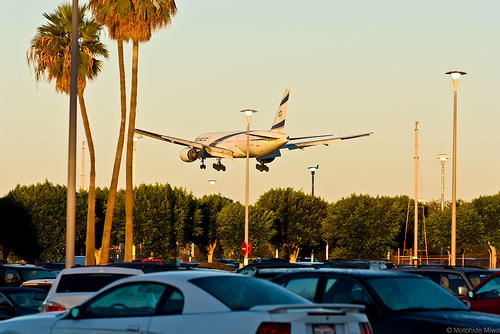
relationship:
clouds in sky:
[0, 0, 500, 200] [38, 22, 479, 209]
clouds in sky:
[0, 0, 500, 200] [152, 44, 490, 202]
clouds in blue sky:
[0, 0, 500, 200] [247, 17, 476, 55]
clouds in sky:
[0, 0, 500, 200] [181, 7, 405, 79]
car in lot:
[246, 250, 446, 332] [7, 242, 490, 330]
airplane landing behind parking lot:
[133, 90, 373, 170] [8, 255, 493, 331]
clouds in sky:
[0, 0, 500, 200] [1, 0, 498, 205]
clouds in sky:
[0, 0, 500, 200] [182, 3, 441, 85]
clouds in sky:
[362, 53, 407, 105] [184, 2, 498, 100]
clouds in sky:
[0, 0, 500, 200] [222, 19, 420, 106]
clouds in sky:
[0, 0, 500, 200] [182, 22, 483, 165]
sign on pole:
[237, 239, 256, 259] [234, 91, 255, 266]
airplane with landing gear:
[133, 88, 374, 172] [194, 153, 277, 174]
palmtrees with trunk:
[88, 0, 178, 264] [82, 111, 101, 242]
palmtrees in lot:
[25, 3, 180, 293] [18, 237, 498, 323]